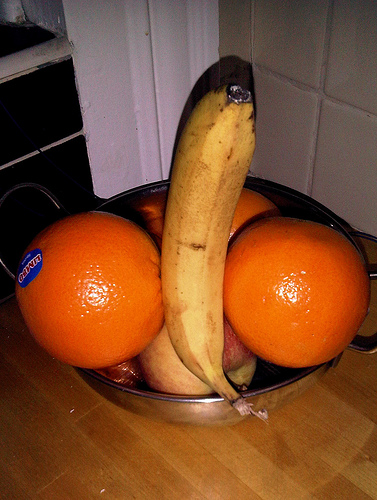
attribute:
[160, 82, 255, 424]
banana — yellow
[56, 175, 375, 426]
fruit bowl — silver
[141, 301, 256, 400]
apple — yellow, green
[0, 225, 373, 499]
table — wood, wooden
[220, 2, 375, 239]
wall — white, tiled